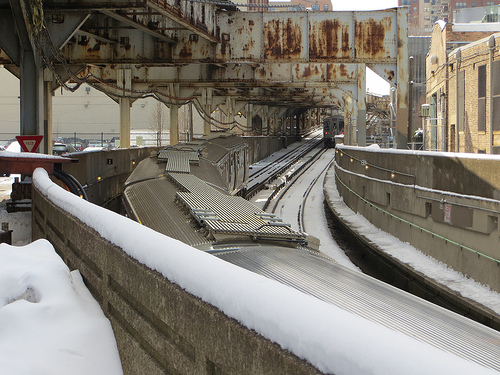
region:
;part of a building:
[248, 1, 262, 8]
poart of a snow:
[282, 291, 329, 373]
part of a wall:
[196, 304, 241, 366]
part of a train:
[353, 281, 380, 316]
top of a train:
[380, 293, 400, 321]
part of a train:
[316, 280, 358, 311]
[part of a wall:
[425, 185, 464, 214]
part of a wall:
[183, 258, 213, 298]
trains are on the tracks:
[9, 3, 493, 373]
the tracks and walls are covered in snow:
[5, 128, 499, 366]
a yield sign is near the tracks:
[15, 135, 47, 177]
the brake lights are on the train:
[317, 108, 343, 143]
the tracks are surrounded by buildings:
[92, 0, 497, 190]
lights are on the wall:
[330, 142, 421, 203]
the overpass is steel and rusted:
[10, 2, 401, 143]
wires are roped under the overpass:
[18, 5, 284, 138]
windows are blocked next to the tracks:
[451, 60, 497, 136]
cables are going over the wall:
[3, 135, 94, 235]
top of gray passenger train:
[139, 151, 204, 188]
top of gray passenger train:
[151, 168, 235, 234]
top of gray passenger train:
[208, 182, 311, 266]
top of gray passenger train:
[271, 240, 361, 290]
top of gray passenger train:
[307, 246, 402, 320]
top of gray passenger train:
[387, 282, 473, 335]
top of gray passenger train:
[130, 141, 250, 196]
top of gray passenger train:
[154, 180, 332, 239]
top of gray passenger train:
[251, 186, 346, 293]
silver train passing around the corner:
[111, 126, 498, 373]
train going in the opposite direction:
[315, 108, 353, 150]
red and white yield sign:
[9, 128, 46, 159]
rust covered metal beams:
[0, 0, 416, 115]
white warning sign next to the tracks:
[438, 203, 458, 226]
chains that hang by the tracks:
[23, 5, 338, 146]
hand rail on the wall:
[330, 163, 499, 293]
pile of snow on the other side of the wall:
[0, 231, 133, 370]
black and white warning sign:
[351, 154, 371, 169]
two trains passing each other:
[98, 110, 499, 374]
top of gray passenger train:
[151, 167, 193, 210]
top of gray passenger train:
[186, 187, 257, 245]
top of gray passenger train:
[234, 215, 289, 262]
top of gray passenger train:
[259, 242, 298, 268]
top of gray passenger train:
[306, 265, 341, 290]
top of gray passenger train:
[344, 285, 397, 310]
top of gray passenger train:
[391, 305, 441, 340]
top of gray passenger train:
[451, 320, 473, 342]